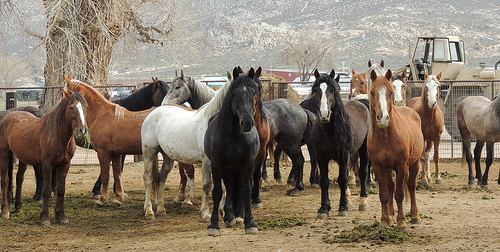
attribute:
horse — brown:
[365, 64, 421, 227]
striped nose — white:
[368, 81, 390, 130]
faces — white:
[308, 65, 400, 130]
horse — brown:
[366, 68, 423, 232]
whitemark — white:
[377, 86, 384, 123]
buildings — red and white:
[199, 65, 359, 87]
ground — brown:
[3, 163, 498, 250]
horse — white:
[140, 73, 233, 214]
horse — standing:
[363, 68, 426, 228]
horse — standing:
[307, 67, 372, 220]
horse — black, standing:
[201, 62, 265, 239]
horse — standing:
[1, 83, 88, 228]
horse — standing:
[411, 68, 446, 184]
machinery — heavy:
[486, 37, 498, 139]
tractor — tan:
[391, 32, 497, 137]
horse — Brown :
[0, 86, 94, 231]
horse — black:
[255, 94, 327, 199]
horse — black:
[109, 74, 172, 112]